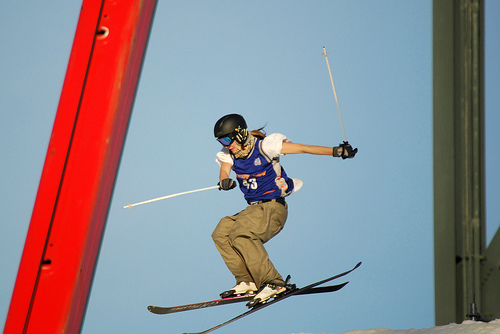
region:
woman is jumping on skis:
[110, 35, 370, 330]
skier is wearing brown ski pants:
[206, 196, 303, 293]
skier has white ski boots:
[225, 265, 285, 304]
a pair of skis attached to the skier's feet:
[133, 255, 364, 330]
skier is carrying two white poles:
[103, 31, 356, 226]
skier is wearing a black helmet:
[211, 107, 250, 144]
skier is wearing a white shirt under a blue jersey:
[213, 125, 290, 177]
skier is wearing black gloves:
[215, 132, 367, 197]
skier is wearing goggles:
[214, 127, 239, 149]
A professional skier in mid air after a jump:
[91, 37, 386, 330]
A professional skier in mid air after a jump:
[110, 35, 367, 328]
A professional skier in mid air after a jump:
[116, 35, 373, 328]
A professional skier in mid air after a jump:
[116, 38, 373, 324]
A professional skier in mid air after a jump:
[110, 37, 377, 327]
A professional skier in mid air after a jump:
[110, 31, 367, 317]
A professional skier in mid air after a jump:
[107, 38, 364, 323]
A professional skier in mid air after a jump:
[111, 40, 368, 323]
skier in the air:
[96, 39, 413, 329]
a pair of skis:
[135, 259, 365, 331]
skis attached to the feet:
[141, 250, 373, 332]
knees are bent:
[197, 210, 264, 257]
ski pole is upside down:
[311, 42, 363, 144]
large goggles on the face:
[206, 132, 241, 152]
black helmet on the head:
[211, 106, 260, 160]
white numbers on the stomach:
[238, 178, 261, 190]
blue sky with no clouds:
[1, 0, 437, 327]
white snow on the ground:
[332, 318, 496, 333]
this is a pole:
[317, 42, 377, 153]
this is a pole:
[120, 178, 223, 223]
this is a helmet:
[211, 110, 251, 141]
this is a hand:
[265, 130, 368, 168]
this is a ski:
[214, 258, 356, 330]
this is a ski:
[145, 282, 365, 309]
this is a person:
[188, 95, 303, 325]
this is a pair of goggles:
[205, 130, 237, 150]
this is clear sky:
[152, 5, 405, 321]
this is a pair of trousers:
[220, 204, 291, 285]